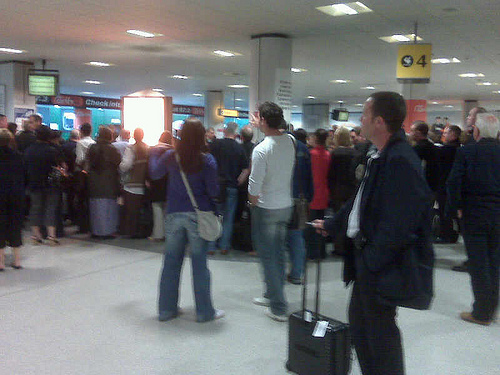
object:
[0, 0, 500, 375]
airport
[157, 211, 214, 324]
jeans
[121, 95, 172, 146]
sign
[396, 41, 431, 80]
sign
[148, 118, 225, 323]
woman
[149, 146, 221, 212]
blue shirt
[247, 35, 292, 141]
pillar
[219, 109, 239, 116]
sign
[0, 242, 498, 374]
white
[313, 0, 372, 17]
light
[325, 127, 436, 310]
jacket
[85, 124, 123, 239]
woman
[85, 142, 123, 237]
dress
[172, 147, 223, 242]
bag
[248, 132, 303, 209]
shirt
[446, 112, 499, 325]
man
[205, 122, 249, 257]
man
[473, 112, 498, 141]
head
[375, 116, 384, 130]
ear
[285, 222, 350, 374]
case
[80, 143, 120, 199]
coat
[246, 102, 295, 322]
man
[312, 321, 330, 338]
tag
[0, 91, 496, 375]
crowd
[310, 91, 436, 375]
man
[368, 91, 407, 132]
brown hair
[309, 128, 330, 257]
lady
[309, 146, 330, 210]
sweater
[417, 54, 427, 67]
4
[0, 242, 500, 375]
floor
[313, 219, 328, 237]
hand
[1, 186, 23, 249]
pants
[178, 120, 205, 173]
hair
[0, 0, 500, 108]
ceiling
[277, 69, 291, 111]
column